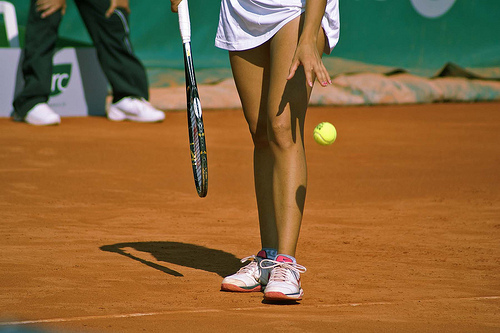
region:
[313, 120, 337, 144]
bright yellow tennis ball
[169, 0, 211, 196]
black tennis racket with a white handle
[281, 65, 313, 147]
shadow of a womans hand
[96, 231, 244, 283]
shadow cast by the tennis player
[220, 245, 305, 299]
pink and white sneakers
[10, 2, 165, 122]
person wearing black pants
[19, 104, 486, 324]
dusty orange colored tennis court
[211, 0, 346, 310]
tennis player wearing a short skirt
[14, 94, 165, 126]
pure white sneakers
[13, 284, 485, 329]
white line on the court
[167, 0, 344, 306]
Woman bouncing a tennis ball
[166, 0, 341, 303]
Woman getting ready to serve a tennis ball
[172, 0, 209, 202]
Black tennis racket with a white handle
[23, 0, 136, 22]
Persons hands on their knees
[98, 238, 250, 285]
Shadow of a female tennis player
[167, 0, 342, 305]
Tennis player wearing a white skirt and tennis shoes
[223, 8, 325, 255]
A pair of tan legs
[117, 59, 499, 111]
Long tarp folded on the ground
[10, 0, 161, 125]
Dark green pants and white tennis shoes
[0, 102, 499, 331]
Light brown dirt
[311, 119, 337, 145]
a yellow tennis ball in the air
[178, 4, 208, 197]
a white and black tennis racket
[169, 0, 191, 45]
white handle to the racket in the woman's right hand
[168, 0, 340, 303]
a woman preparing to serve the tennis ball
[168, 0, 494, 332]
a professional tennis competitor on the court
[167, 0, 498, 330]
a tennis player ready to serve the ball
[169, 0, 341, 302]
a professional tennis preparing to serve a right swing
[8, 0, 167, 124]
a man standing behind the tennis court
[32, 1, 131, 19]
the hands of the man resting on the knees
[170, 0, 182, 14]
the tennis player's right pointer finger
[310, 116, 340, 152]
A tennis ball in the photo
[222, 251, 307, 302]
White shoes in the photo.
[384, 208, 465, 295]
Dirt track in the photo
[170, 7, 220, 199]
A tennis racket in the photo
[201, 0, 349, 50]
A white dress in the photo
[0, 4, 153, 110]
Black trousers in the photo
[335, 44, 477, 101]
Tartan in the background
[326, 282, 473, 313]
White markings in the photo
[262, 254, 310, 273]
Shoe lace in the photo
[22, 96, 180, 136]
White shoes in the background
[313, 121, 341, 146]
a small green tennis ball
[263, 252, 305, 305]
a woman's tennis shoe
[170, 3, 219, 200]
a black and white tennis racket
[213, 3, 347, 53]
part of a woman's white skirt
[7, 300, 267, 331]
a long white line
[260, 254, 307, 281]
a white shoestring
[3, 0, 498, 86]
a large green tarp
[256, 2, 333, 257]
the leg of a woman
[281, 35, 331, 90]
the hand of a woman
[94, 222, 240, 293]
the shadow of a woman